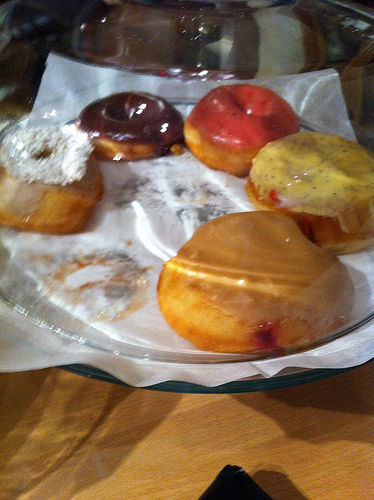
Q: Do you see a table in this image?
A: Yes, there is a table.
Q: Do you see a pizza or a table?
A: Yes, there is a table.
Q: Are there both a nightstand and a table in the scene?
A: No, there is a table but no nightstands.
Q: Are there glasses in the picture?
A: No, there are no glasses.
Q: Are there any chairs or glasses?
A: No, there are no glasses or chairs.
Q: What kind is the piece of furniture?
A: The piece of furniture is a table.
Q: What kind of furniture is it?
A: The piece of furniture is a table.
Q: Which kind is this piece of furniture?
A: This is a table.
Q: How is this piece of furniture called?
A: This is a table.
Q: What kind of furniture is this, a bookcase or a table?
A: This is a table.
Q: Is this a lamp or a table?
A: This is a table.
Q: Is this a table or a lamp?
A: This is a table.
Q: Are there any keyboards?
A: No, there are no keyboards.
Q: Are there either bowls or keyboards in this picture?
A: No, there are no keyboards or bowls.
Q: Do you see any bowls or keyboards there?
A: No, there are no keyboards or bowls.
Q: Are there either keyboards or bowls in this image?
A: No, there are no keyboards or bowls.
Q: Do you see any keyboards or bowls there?
A: No, there are no keyboards or bowls.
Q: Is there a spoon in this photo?
A: No, there are no spoons.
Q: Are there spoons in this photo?
A: No, there are no spoons.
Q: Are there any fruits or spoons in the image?
A: No, there are no spoons or fruits.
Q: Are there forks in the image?
A: No, there are no forks.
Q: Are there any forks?
A: No, there are no forks.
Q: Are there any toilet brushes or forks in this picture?
A: No, there are no forks or toilet brushes.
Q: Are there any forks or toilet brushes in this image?
A: No, there are no forks or toilet brushes.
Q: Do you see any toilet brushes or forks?
A: No, there are no forks or toilet brushes.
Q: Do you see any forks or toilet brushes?
A: No, there are no forks or toilet brushes.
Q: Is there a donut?
A: Yes, there is a donut.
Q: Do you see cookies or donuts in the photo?
A: Yes, there is a donut.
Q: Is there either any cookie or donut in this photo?
A: Yes, there is a donut.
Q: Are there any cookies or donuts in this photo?
A: Yes, there is a donut.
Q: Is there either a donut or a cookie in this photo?
A: Yes, there is a donut.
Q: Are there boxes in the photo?
A: No, there are no boxes.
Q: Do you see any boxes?
A: No, there are no boxes.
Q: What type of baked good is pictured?
A: The baked good is a donut.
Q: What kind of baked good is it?
A: The food is a donut.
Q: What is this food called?
A: This is a donut.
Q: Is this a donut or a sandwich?
A: This is a donut.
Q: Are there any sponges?
A: No, there are no sponges.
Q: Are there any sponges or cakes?
A: No, there are no sponges or cakes.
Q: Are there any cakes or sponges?
A: No, there are no sponges or cakes.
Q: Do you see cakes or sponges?
A: No, there are no sponges or cakes.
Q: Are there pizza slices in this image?
A: No, there are no pizza slices.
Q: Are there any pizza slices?
A: No, there are no pizza slices.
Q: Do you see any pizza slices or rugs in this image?
A: No, there are no pizza slices or rugs.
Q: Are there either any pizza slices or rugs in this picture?
A: No, there are no pizza slices or rugs.